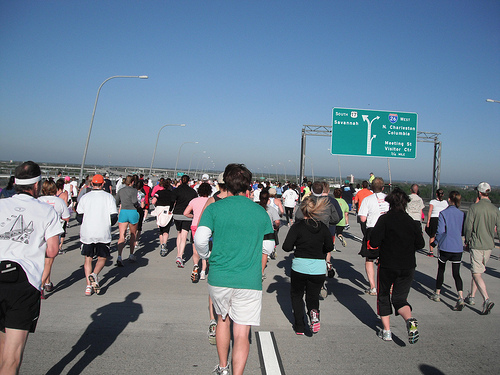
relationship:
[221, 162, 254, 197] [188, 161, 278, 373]
head of person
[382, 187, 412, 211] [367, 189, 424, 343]
head of person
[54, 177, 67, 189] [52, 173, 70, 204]
head of person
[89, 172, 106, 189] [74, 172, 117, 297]
head part of jogger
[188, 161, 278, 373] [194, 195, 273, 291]
person wearing shirt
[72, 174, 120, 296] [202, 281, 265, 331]
person wearing tan shorts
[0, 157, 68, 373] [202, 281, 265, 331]
person wearing tan shorts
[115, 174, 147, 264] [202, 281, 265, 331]
person wearing tan shorts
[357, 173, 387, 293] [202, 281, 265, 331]
person wearing tan shorts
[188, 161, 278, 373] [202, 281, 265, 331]
person wearing tan shorts